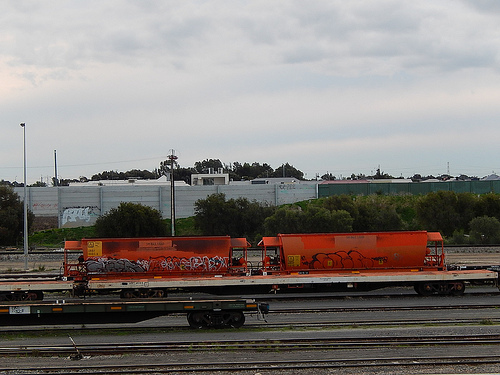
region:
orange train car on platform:
[61, 241, 248, 284]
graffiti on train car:
[296, 249, 363, 271]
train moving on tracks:
[1, 238, 499, 327]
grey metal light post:
[20, 123, 31, 253]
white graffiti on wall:
[58, 208, 93, 227]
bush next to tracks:
[195, 194, 271, 231]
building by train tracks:
[13, 181, 499, 231]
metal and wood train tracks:
[6, 338, 499, 363]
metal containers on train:
[62, 236, 451, 281]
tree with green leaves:
[235, 161, 276, 179]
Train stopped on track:
[22, 205, 457, 347]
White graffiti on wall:
[43, 181, 113, 243]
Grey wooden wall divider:
[4, 162, 337, 261]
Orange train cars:
[70, 230, 490, 302]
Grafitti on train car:
[53, 249, 432, 285]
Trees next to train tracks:
[24, 183, 496, 255]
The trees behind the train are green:
[10, 170, 495, 260]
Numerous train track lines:
[10, 245, 496, 371]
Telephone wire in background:
[0, 140, 200, 175]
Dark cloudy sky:
[4, 9, 497, 190]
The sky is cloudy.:
[53, 29, 417, 169]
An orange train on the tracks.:
[53, 218, 455, 289]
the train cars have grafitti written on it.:
[91, 241, 383, 278]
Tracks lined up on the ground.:
[316, 288, 459, 371]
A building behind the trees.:
[29, 176, 314, 228]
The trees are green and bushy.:
[198, 192, 478, 227]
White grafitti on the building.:
[50, 193, 114, 231]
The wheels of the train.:
[406, 279, 483, 298]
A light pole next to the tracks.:
[18, 122, 34, 247]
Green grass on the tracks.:
[102, 326, 307, 349]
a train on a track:
[50, 224, 465, 302]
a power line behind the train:
[152, 135, 202, 241]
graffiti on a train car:
[64, 256, 238, 285]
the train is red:
[50, 238, 490, 296]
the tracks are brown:
[0, 239, 478, 371]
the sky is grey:
[37, 3, 490, 157]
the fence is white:
[20, 164, 497, 218]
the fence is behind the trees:
[22, 159, 464, 254]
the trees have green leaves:
[180, 190, 495, 235]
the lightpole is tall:
[11, 120, 32, 258]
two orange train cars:
[45, 226, 452, 301]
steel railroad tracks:
[47, 325, 478, 364]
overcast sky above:
[64, 29, 344, 107]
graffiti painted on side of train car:
[301, 245, 389, 271]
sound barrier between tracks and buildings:
[19, 180, 319, 237]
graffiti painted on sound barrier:
[55, 202, 104, 229]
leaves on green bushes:
[259, 192, 481, 235]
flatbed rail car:
[94, 262, 499, 301]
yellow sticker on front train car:
[85, 236, 106, 263]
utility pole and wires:
[378, 150, 477, 180]